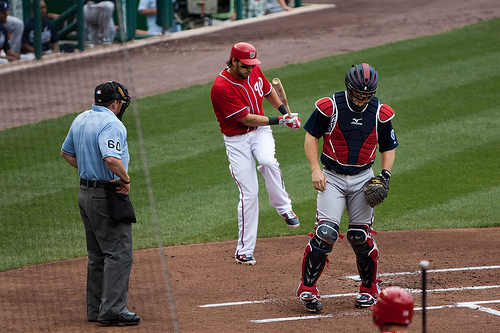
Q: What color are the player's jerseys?
A: Red and black.